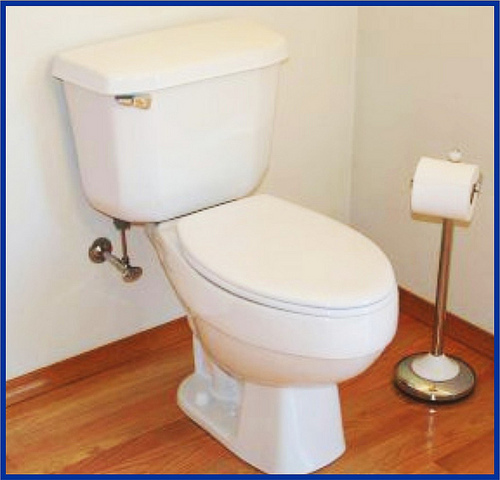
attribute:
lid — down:
[175, 192, 397, 312]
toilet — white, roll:
[48, 12, 403, 479]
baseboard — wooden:
[8, 317, 188, 421]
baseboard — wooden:
[404, 284, 498, 364]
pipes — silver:
[85, 215, 137, 272]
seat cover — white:
[163, 192, 408, 320]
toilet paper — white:
[408, 150, 485, 226]